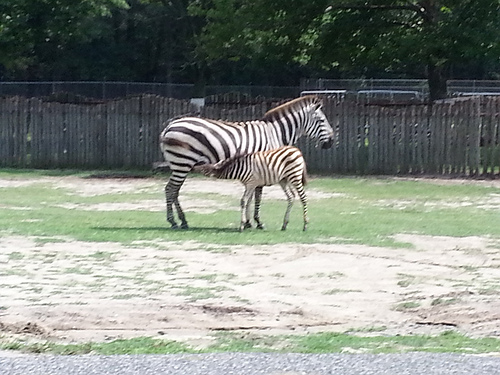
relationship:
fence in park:
[3, 90, 484, 179] [4, 79, 496, 369]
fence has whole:
[3, 90, 484, 179] [350, 119, 375, 170]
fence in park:
[3, 90, 484, 179] [1, 2, 497, 372]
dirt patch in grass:
[132, 250, 422, 318] [219, 331, 494, 353]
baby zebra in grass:
[190, 145, 310, 232] [14, 172, 438, 364]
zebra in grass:
[151, 97, 353, 183] [14, 172, 438, 364]